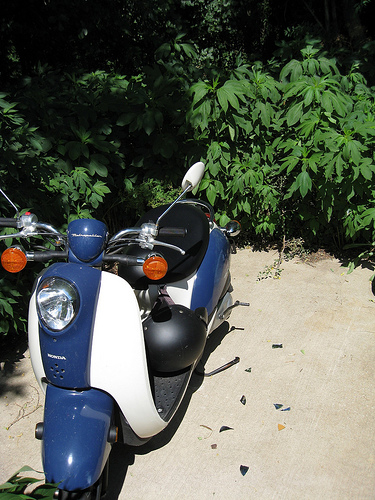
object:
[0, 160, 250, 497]
bike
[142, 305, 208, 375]
helmet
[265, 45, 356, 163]
trees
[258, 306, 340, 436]
road